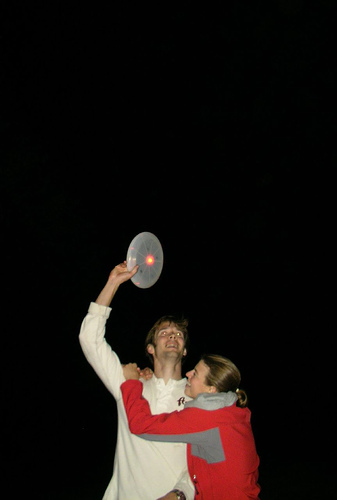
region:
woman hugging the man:
[121, 323, 225, 446]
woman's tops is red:
[149, 409, 247, 466]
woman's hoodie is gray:
[182, 390, 244, 410]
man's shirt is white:
[83, 333, 175, 492]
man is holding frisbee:
[117, 226, 176, 381]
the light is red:
[108, 223, 177, 298]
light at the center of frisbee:
[123, 237, 184, 284]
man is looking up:
[106, 295, 232, 392]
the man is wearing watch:
[158, 475, 183, 498]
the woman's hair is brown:
[207, 353, 252, 414]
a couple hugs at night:
[73, 243, 261, 496]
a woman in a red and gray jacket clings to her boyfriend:
[188, 358, 268, 499]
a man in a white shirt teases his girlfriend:
[101, 265, 197, 498]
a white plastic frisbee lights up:
[119, 215, 172, 285]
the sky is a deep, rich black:
[19, 75, 285, 202]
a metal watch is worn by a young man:
[168, 491, 188, 498]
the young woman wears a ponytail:
[184, 353, 247, 401]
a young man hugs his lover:
[73, 268, 185, 498]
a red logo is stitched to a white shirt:
[175, 396, 190, 408]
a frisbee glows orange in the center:
[127, 235, 168, 284]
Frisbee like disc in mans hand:
[132, 230, 162, 288]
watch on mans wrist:
[172, 486, 187, 498]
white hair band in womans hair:
[235, 386, 239, 392]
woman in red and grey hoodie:
[178, 356, 239, 498]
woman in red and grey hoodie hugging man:
[122, 364, 300, 491]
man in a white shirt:
[111, 319, 183, 499]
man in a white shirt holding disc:
[85, 220, 184, 498]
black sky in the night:
[201, 151, 313, 308]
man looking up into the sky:
[96, 228, 188, 474]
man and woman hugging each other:
[74, 223, 251, 498]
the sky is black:
[93, 137, 244, 192]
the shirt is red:
[213, 441, 269, 493]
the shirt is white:
[130, 452, 163, 475]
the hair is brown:
[217, 362, 241, 384]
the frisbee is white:
[129, 248, 165, 277]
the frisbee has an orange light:
[144, 253, 159, 264]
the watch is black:
[170, 485, 186, 497]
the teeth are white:
[183, 379, 191, 386]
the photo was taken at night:
[0, 8, 333, 490]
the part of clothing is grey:
[154, 434, 230, 464]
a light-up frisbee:
[124, 225, 165, 295]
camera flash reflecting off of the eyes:
[159, 327, 184, 339]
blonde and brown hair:
[143, 309, 194, 360]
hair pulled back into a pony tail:
[197, 349, 251, 407]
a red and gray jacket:
[117, 375, 265, 498]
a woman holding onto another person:
[112, 350, 264, 498]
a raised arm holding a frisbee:
[72, 213, 169, 403]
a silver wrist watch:
[169, 486, 189, 498]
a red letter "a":
[175, 394, 186, 408]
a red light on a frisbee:
[145, 253, 156, 265]